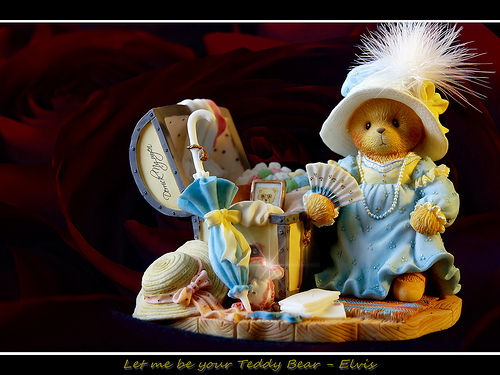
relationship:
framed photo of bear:
[249, 177, 287, 212] [257, 184, 277, 204]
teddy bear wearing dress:
[303, 21, 495, 300] [312, 151, 463, 301]